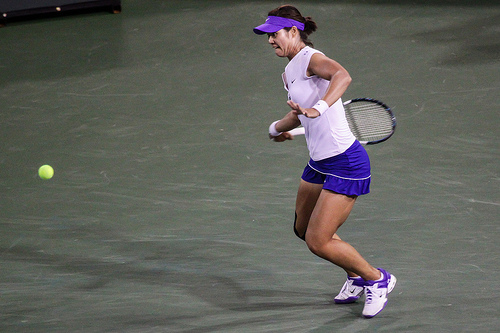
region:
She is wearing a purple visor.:
[240, 2, 342, 73]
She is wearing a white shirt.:
[245, 7, 384, 199]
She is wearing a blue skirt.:
[245, 7, 379, 239]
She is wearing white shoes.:
[323, 253, 411, 325]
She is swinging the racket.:
[258, 74, 417, 154]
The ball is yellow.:
[32, 153, 74, 212]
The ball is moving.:
[12, 131, 87, 212]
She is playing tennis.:
[238, 7, 422, 321]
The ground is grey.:
[107, 95, 245, 275]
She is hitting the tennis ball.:
[8, 6, 435, 328]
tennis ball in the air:
[19, 148, 89, 217]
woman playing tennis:
[228, 7, 410, 331]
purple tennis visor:
[247, 10, 319, 47]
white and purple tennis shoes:
[314, 267, 419, 325]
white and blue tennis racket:
[250, 94, 422, 149]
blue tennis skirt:
[285, 148, 402, 209]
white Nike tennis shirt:
[252, 41, 375, 163]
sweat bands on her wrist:
[296, 87, 336, 127]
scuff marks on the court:
[103, 143, 253, 273]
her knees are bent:
[277, 165, 402, 287]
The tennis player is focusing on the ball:
[209, 7, 435, 317]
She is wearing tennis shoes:
[318, 240, 408, 315]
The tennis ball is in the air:
[18, 155, 61, 184]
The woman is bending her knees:
[267, 180, 360, 274]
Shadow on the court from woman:
[17, 232, 254, 332]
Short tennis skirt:
[304, 148, 383, 193]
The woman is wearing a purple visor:
[242, 8, 323, 38]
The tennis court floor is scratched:
[51, 30, 213, 219]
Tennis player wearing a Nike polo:
[267, 45, 366, 156]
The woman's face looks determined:
[263, 21, 300, 57]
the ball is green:
[36, 160, 58, 184]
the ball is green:
[42, 166, 79, 208]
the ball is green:
[40, 155, 51, 184]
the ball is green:
[42, 165, 60, 182]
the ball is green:
[48, 170, 58, 177]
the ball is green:
[42, 173, 62, 193]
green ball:
[36, 164, 53, 179]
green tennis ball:
[37, 164, 55, 178]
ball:
[35, 164, 56, 178]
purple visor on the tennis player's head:
[248, 14, 306, 34]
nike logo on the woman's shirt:
[287, 74, 298, 86]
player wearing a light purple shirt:
[249, 4, 353, 164]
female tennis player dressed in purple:
[248, 7, 403, 320]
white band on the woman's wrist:
[313, 93, 330, 117]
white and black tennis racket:
[266, 94, 402, 146]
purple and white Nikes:
[333, 260, 403, 320]